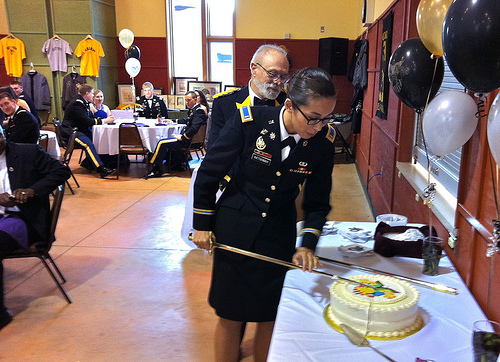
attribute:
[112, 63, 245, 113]
photos — framed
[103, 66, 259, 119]
documents — framed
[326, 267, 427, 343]
cake — special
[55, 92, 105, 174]
uniform — military, dress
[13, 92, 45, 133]
uniform — military, dress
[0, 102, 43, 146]
uniform — military, dress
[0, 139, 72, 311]
uniform — military, dress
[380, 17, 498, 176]
balloons — Black , white 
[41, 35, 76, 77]
t-shirt — yellow, gray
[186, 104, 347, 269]
jacket — Stripes 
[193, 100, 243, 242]
sleeve — Stripes 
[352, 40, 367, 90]
black backpack — black 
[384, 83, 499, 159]
balloon — helium filled , white 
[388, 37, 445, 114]
balloon — black, helium , filled 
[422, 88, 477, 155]
balloon — white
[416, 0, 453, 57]
balloon — gold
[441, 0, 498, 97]
balloon — black, filled , helium 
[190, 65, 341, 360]
officer — decorated, military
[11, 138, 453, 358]
floor — shiny 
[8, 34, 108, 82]
shirts — yellow 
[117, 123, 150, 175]
chair — black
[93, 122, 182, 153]
tablecloth — white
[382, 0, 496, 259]
balloons — Various colored 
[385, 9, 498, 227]
balloons — helium filled 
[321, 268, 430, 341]
cake — white , frosted , yellow 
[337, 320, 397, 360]
cake server — silver